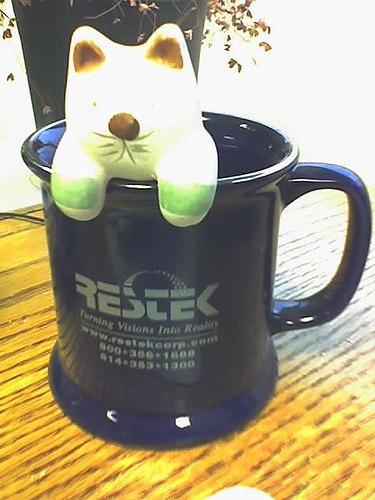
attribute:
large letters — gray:
[70, 272, 225, 322]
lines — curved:
[125, 269, 156, 285]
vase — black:
[9, 0, 212, 131]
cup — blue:
[24, 114, 374, 463]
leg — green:
[50, 141, 111, 211]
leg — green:
[143, 162, 209, 220]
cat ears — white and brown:
[63, 17, 199, 73]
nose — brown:
[103, 110, 141, 141]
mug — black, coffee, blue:
[19, 110, 370, 450]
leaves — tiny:
[1, 3, 277, 107]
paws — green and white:
[51, 171, 107, 223]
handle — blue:
[274, 162, 371, 331]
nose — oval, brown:
[106, 111, 141, 143]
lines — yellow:
[292, 429, 343, 475]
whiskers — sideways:
[89, 127, 155, 169]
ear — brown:
[152, 27, 187, 79]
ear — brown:
[62, 30, 105, 69]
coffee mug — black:
[18, 112, 371, 450]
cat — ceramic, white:
[51, 19, 221, 226]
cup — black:
[23, 17, 374, 486]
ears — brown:
[69, 34, 185, 72]